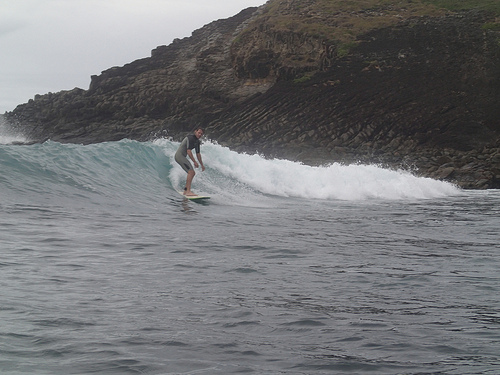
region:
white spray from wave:
[269, 159, 340, 206]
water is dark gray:
[309, 254, 324, 266]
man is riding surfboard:
[170, 133, 237, 213]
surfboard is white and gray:
[180, 185, 215, 212]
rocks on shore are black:
[352, 111, 409, 163]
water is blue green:
[58, 159, 122, 213]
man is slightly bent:
[178, 130, 202, 174]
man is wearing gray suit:
[185, 138, 190, 183]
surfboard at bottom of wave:
[172, 173, 212, 194]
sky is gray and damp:
[16, 88, 27, 92]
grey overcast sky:
[0, 2, 273, 115]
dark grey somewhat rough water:
[10, 197, 498, 372]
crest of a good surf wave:
[2, 136, 178, 160]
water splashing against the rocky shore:
[211, 120, 463, 200]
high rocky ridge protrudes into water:
[0, 3, 487, 192]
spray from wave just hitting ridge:
[1, 110, 38, 148]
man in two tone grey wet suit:
[172, 122, 214, 192]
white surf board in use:
[173, 180, 218, 203]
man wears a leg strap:
[171, 165, 206, 201]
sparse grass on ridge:
[208, 0, 494, 82]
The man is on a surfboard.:
[154, 119, 217, 216]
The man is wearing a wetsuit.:
[163, 118, 213, 210]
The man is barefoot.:
[166, 120, 221, 205]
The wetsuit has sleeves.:
[164, 118, 215, 204]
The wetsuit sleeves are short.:
[165, 116, 217, 207]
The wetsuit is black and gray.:
[166, 113, 215, 215]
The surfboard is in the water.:
[138, 114, 263, 373]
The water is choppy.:
[1, 115, 498, 372]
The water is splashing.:
[0, 108, 499, 373]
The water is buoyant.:
[3, 114, 499, 374]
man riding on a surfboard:
[175, 125, 209, 202]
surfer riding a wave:
[161, 121, 286, 211]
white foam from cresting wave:
[208, 138, 394, 210]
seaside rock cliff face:
[88, 6, 481, 193]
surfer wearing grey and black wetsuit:
[173, 126, 214, 201]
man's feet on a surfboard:
[169, 180, 210, 202]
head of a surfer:
[193, 125, 205, 139]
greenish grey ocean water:
[64, 217, 414, 358]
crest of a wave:
[4, 136, 173, 159]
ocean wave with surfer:
[78, 125, 250, 224]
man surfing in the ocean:
[162, 104, 240, 206]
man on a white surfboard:
[148, 105, 245, 215]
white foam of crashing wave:
[234, 165, 436, 202]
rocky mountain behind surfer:
[71, 18, 472, 137]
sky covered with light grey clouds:
[12, 15, 102, 60]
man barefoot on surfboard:
[152, 116, 232, 205]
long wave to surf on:
[7, 145, 456, 205]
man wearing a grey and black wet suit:
[157, 112, 243, 208]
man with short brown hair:
[162, 115, 218, 198]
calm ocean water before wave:
[146, 213, 498, 360]